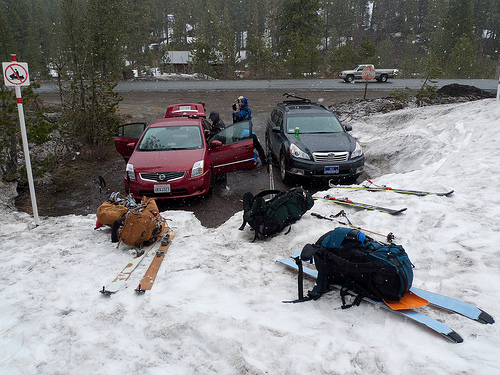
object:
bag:
[288, 223, 421, 316]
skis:
[273, 219, 498, 343]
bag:
[97, 188, 165, 246]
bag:
[236, 181, 312, 244]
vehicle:
[114, 95, 255, 207]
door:
[207, 119, 256, 176]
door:
[112, 121, 145, 156]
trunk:
[166, 102, 205, 117]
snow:
[412, 52, 420, 60]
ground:
[19, 226, 55, 250]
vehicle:
[265, 92, 366, 191]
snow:
[361, 121, 380, 144]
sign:
[361, 66, 376, 81]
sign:
[1, 61, 31, 88]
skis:
[103, 224, 143, 295]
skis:
[136, 229, 189, 299]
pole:
[14, 89, 55, 229]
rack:
[270, 88, 322, 104]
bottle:
[289, 122, 301, 141]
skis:
[318, 174, 457, 215]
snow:
[388, 196, 408, 206]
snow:
[241, 242, 266, 265]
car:
[338, 60, 400, 84]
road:
[352, 82, 392, 90]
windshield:
[285, 110, 344, 133]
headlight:
[186, 160, 208, 179]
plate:
[149, 185, 172, 193]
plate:
[325, 164, 340, 174]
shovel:
[380, 288, 429, 313]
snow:
[418, 167, 447, 187]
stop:
[363, 70, 374, 79]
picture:
[6, 64, 29, 84]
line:
[11, 65, 21, 81]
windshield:
[139, 124, 203, 153]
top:
[296, 126, 302, 131]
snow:
[46, 322, 91, 350]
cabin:
[149, 46, 203, 76]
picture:
[160, 50, 226, 73]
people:
[200, 106, 235, 142]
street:
[152, 81, 227, 92]